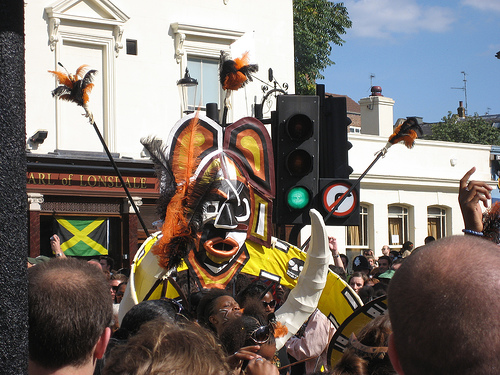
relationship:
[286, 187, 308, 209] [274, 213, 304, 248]
light on pole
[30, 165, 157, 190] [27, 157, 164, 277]
letter on wall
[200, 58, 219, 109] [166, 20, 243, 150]
window with frame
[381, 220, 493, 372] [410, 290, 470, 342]
head with hair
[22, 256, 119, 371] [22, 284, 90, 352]
head with hair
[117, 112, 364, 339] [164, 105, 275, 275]
person with mask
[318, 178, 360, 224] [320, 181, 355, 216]
sign with sign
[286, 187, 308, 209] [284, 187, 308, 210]
light with green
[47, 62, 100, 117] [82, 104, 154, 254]
feathers on stick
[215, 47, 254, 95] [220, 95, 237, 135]
feathers on stick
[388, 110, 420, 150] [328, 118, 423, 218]
feathers are on a stick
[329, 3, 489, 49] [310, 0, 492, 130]
clouds are on a sky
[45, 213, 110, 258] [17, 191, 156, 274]
flag on a wall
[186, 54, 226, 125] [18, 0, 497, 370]
window on side of building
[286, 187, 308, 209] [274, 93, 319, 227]
light lit up on street light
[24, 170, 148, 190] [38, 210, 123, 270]
business name painted above door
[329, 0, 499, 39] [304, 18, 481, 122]
clouds in sky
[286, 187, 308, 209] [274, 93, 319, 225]
light on street light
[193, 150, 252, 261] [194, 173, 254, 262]
mask on face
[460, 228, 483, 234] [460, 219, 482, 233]
bracelet on wrist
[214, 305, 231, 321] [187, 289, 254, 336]
face paint on woman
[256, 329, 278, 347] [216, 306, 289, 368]
sunglasses on head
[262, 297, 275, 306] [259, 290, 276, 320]
sunglasses on face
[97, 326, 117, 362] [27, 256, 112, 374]
ear of person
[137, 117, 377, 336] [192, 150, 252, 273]
person wearing mask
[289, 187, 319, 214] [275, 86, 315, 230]
light on traffic signal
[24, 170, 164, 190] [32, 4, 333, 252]
writing on building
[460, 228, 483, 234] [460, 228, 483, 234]
bracelet on bracelet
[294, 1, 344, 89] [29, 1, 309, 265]
tree next to building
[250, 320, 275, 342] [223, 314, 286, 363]
sunglasses on top of head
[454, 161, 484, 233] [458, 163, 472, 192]
hand with finger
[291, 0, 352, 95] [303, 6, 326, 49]
tree with leaves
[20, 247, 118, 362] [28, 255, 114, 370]
back of head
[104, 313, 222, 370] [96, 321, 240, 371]
someone with hair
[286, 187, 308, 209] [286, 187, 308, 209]
light on light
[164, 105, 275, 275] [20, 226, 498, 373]
mask in middle of street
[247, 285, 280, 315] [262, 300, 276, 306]
person wearing sunglasses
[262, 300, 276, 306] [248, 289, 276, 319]
sunglasses on face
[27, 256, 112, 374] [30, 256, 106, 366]
person has hair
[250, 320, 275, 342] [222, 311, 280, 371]
sunglasses on head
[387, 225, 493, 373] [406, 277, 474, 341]
person has hair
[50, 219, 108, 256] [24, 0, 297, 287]
flag on building